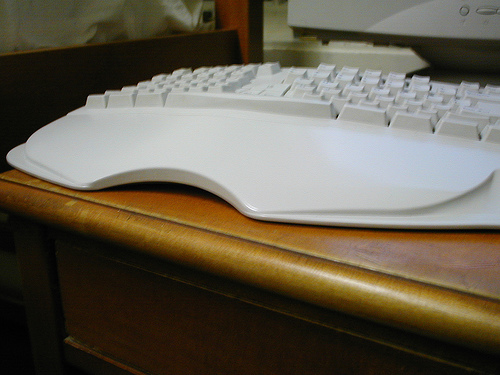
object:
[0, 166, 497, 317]
board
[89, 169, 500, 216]
curve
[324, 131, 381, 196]
ground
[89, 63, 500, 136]
key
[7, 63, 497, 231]
key board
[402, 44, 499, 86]
base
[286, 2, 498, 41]
monitor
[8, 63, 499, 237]
keyboard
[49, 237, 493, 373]
drawer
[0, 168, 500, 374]
desk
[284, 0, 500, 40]
computer monitor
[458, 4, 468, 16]
button